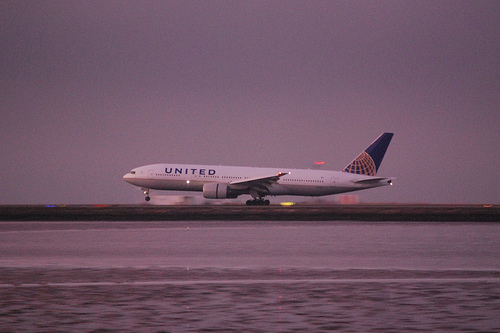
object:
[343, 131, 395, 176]
tail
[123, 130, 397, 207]
airplane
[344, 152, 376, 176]
design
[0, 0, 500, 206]
sky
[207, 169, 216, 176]
writing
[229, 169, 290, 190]
wing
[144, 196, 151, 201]
front wheels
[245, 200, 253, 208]
back wheels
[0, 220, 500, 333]
water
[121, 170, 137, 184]
nose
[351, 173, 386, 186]
wing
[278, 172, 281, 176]
light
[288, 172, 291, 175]
light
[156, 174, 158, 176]
passenger windows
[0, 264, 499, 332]
ripples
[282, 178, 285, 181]
passenger windows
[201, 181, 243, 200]
side engine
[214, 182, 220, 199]
stripe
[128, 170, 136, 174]
windshield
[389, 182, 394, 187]
light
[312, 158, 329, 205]
tower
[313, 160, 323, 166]
lights